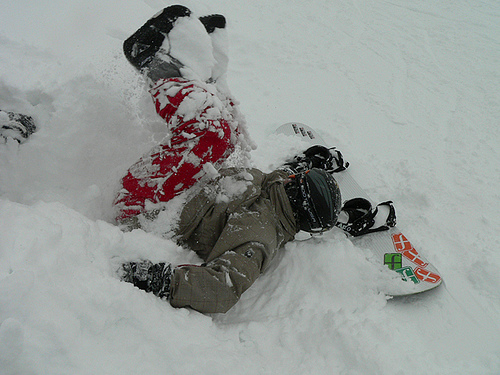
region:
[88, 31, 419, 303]
A man laying in the snow.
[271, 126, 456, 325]
A snowboard in the snow.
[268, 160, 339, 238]
A person wearing a ski mask.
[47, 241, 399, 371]
Snow is on the ground.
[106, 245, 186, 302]
A person is wearing black gloves.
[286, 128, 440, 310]
The snowboard is laying behind the person.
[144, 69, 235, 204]
the person is wearing red pants.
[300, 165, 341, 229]
The person is wearing hat over head.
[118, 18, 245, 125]
The person leg is in the air.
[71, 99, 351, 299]
The person is laying on their back.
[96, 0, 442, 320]
snowboarder who has fallen in the snow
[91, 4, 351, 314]
snow covered snow boarder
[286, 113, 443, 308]
white snowboard with graphics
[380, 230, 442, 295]
green and orange images of boxes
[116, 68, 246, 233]
red snow pants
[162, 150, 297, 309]
grey winter coat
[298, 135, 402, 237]
black foot straps on a snowboard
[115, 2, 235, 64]
black snowboarding boots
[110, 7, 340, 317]
person with his legs in the air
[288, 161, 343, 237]
black and grey helmet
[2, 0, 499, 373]
Deep snow on the ground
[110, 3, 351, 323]
A snowboarder in the snow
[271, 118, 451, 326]
A mostly white snowboard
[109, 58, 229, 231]
Red snow pants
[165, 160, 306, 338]
A grey winter coat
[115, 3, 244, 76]
Boots of a snowboarder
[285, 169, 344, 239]
A black helmet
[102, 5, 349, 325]
A man who fell in the snow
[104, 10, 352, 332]
A snowboarder who fell of the snowboard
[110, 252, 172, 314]
A black ski glove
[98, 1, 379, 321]
snowboarder falls on the snow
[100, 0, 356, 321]
man wears a black helmet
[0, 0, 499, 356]
man on the snow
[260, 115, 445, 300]
a white snowboard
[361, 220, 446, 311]
orange and green shapes on nose of snowboard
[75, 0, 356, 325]
a person with feet up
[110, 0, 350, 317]
snowboarder wears red pants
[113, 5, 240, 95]
black snow boots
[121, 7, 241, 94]
boots are covered with snow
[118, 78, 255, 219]
red pants covered with snow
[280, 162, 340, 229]
helmet on man in the snow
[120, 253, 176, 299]
left glove in the snow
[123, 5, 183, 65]
left foot in the snow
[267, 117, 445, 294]
snowboard in the snow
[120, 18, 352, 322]
man laying in the snow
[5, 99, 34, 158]
foot buried in the snow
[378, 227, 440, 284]
colored design in the snow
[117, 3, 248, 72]
feet buried in the snow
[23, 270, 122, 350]
snow on the ground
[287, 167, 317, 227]
goggles on man in snow